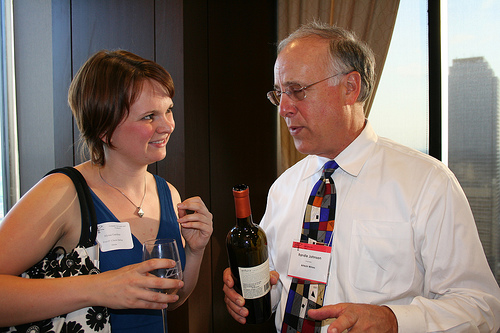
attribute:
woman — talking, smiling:
[3, 40, 215, 332]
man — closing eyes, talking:
[222, 21, 490, 332]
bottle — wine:
[222, 181, 274, 332]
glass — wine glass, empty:
[144, 235, 185, 331]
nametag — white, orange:
[286, 238, 341, 286]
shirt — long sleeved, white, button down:
[246, 128, 488, 332]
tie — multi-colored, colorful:
[286, 165, 346, 332]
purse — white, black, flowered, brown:
[11, 161, 111, 332]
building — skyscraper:
[441, 52, 499, 283]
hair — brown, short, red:
[66, 53, 176, 164]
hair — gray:
[273, 25, 383, 99]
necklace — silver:
[99, 170, 157, 222]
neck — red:
[232, 184, 253, 219]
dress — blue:
[82, 170, 184, 332]